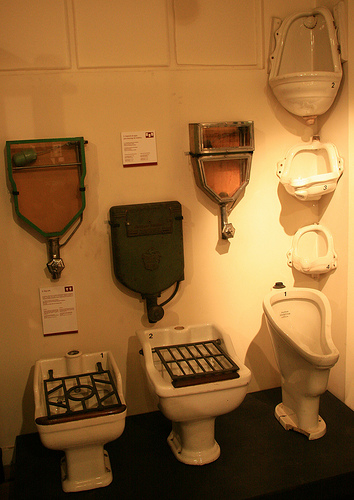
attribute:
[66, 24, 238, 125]
wall — here, white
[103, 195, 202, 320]
tank — green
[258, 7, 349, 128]
urnial — highest, here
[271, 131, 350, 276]
urinals — collected, for men, mounted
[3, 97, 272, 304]
tanks — small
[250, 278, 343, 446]
urinal — tall, broken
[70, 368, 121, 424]
part — black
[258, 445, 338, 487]
box — black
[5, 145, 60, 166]
thing — green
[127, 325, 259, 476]
toilet — here, white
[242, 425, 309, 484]
floor — here, black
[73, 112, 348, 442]
toilets — here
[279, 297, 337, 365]
bowl — white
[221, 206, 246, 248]
flush — here, metallic